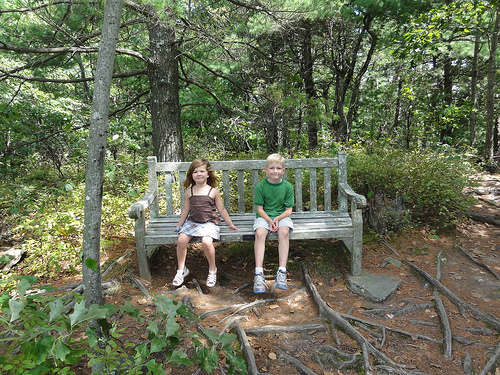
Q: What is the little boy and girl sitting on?
A: A bench.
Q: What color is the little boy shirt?
A: Green.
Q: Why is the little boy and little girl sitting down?
A: To take a picture.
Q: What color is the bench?
A: Brown.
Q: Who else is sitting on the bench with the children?
A: No one.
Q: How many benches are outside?
A: One.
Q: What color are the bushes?
A: Green.